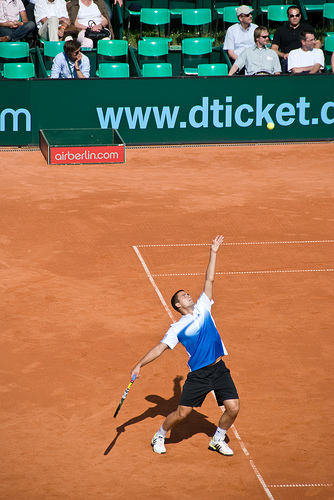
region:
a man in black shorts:
[132, 239, 259, 462]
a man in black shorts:
[146, 302, 217, 495]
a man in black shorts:
[175, 287, 233, 470]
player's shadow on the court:
[115, 380, 248, 440]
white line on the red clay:
[247, 458, 273, 480]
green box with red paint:
[34, 120, 134, 172]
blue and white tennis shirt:
[154, 314, 243, 369]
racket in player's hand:
[96, 377, 180, 419]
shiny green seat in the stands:
[134, 29, 179, 65]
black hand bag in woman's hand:
[77, 17, 122, 44]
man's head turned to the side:
[45, 34, 104, 93]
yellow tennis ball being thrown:
[243, 107, 298, 146]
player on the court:
[85, 240, 267, 429]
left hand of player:
[199, 238, 234, 258]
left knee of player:
[215, 396, 246, 427]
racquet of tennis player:
[104, 375, 148, 410]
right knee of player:
[172, 396, 192, 421]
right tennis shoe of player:
[136, 426, 183, 453]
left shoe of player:
[199, 425, 247, 463]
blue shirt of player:
[170, 325, 255, 374]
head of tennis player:
[159, 287, 204, 319]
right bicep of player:
[141, 330, 176, 361]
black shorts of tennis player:
[170, 356, 258, 416]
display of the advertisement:
[90, 81, 332, 156]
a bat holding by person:
[112, 369, 145, 421]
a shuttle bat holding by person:
[103, 382, 139, 425]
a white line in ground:
[224, 422, 275, 497]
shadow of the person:
[151, 383, 211, 453]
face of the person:
[169, 283, 191, 312]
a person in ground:
[102, 240, 296, 460]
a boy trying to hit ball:
[84, 240, 326, 479]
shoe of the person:
[131, 421, 178, 461]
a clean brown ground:
[18, 188, 308, 470]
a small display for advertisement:
[90, 84, 330, 148]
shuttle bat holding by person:
[105, 369, 150, 420]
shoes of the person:
[147, 424, 281, 473]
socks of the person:
[159, 426, 178, 440]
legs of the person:
[158, 406, 242, 441]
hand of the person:
[200, 222, 240, 286]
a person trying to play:
[89, 227, 312, 471]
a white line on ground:
[149, 271, 263, 492]